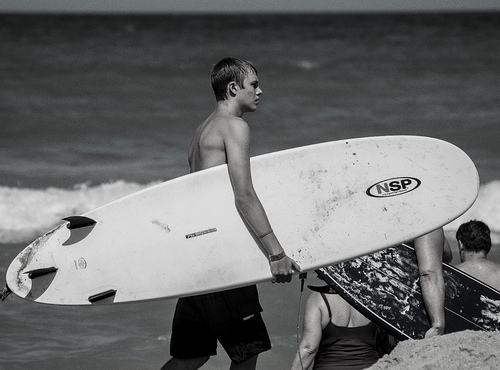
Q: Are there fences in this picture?
A: No, there are no fences.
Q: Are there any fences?
A: No, there are no fences.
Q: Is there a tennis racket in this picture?
A: No, there are no rackets.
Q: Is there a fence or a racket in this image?
A: No, there are no rackets or fences.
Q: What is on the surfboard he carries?
A: The logo is on the surfboard.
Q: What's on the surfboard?
A: The logo is on the surfboard.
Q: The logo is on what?
A: The logo is on the surfboard.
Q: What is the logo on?
A: The logo is on the surfboard.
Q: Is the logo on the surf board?
A: Yes, the logo is on the surf board.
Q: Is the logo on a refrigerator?
A: No, the logo is on the surf board.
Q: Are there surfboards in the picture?
A: Yes, there is a surfboard.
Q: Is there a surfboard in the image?
A: Yes, there is a surfboard.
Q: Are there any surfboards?
A: Yes, there is a surfboard.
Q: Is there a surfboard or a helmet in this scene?
A: Yes, there is a surfboard.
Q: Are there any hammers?
A: No, there are no hammers.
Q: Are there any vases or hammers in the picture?
A: No, there are no hammers or vases.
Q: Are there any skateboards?
A: No, there are no skateboards.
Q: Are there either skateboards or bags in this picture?
A: No, there are no skateboards or bags.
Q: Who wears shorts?
A: The guy wears shorts.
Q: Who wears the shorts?
A: The guy wears shorts.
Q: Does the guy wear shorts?
A: Yes, the guy wears shorts.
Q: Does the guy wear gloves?
A: No, the guy wears shorts.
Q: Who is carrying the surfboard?
A: The guy is carrying the surfboard.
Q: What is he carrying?
A: The guy is carrying a surfboard.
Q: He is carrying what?
A: The guy is carrying a surfboard.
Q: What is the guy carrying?
A: The guy is carrying a surfboard.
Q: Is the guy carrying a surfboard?
A: Yes, the guy is carrying a surfboard.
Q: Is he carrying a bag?
A: No, the guy is carrying a surfboard.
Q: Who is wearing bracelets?
A: The guy is wearing bracelets.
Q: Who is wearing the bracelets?
A: The guy is wearing bracelets.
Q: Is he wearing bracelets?
A: Yes, the guy is wearing bracelets.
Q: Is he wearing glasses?
A: No, the guy is wearing bracelets.